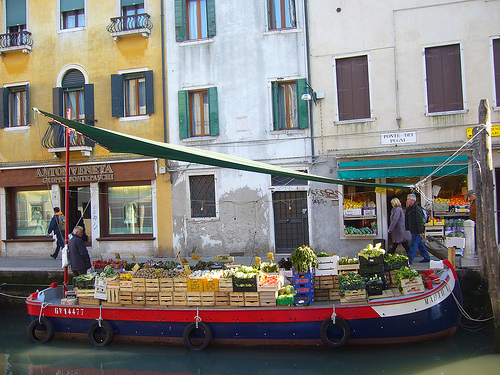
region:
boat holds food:
[23, 106, 472, 351]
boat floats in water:
[21, 106, 459, 342]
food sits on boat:
[91, 249, 423, 307]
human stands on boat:
[66, 223, 90, 277]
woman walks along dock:
[384, 192, 408, 257]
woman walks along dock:
[402, 193, 431, 260]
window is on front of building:
[173, 87, 220, 138]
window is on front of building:
[263, 78, 312, 131]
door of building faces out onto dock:
[270, 171, 309, 256]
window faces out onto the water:
[48, 64, 93, 152]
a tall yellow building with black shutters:
[0, 1, 175, 260]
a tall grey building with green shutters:
[160, 0, 312, 260]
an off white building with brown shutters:
[311, 1, 498, 257]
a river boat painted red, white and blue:
[25, 253, 462, 348]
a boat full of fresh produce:
[27, 239, 466, 349]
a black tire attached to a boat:
[180, 305, 212, 352]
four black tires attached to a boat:
[27, 304, 352, 352]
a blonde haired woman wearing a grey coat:
[386, 197, 409, 260]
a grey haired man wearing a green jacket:
[403, 190, 433, 264]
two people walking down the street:
[386, 192, 430, 264]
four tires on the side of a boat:
[26, 309, 354, 355]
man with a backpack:
[43, 199, 71, 266]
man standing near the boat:
[66, 222, 95, 290]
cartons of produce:
[63, 248, 443, 310]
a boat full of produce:
[23, 258, 476, 358]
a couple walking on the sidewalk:
[380, 190, 435, 268]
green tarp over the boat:
[35, 106, 421, 196]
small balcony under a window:
[36, 110, 105, 166]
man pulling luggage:
[400, 188, 431, 267]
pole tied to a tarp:
[465, 93, 499, 335]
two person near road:
[34, 202, 138, 328]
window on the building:
[156, 140, 244, 240]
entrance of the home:
[252, 175, 333, 281]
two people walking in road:
[374, 170, 450, 285]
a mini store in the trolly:
[95, 256, 426, 316]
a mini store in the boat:
[38, 215, 480, 364]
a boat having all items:
[29, 200, 474, 359]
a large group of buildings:
[1, 10, 491, 140]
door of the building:
[261, 173, 333, 290]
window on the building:
[179, 91, 214, 138]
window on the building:
[187, 175, 212, 220]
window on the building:
[275, 196, 302, 253]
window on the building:
[112, 185, 152, 230]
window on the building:
[330, 56, 367, 118]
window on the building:
[434, 54, 455, 106]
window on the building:
[21, 198, 45, 235]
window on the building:
[3, 87, 26, 122]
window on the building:
[125, 83, 142, 116]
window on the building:
[62, 8, 87, 32]